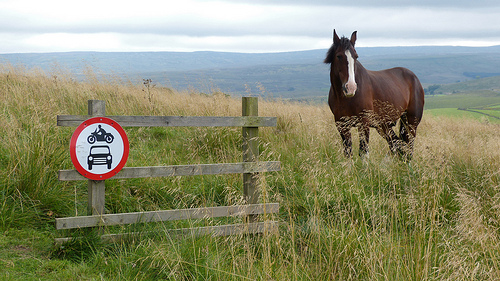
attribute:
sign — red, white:
[69, 121, 126, 180]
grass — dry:
[41, 63, 496, 274]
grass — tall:
[6, 61, 493, 279]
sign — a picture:
[67, 116, 132, 179]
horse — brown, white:
[323, 28, 425, 162]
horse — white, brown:
[308, 25, 444, 175]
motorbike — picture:
[82, 123, 120, 147]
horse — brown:
[328, 35, 424, 158]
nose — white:
[338, 47, 360, 96]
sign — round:
[66, 111, 134, 186]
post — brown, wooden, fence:
[46, 94, 217, 237]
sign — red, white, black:
[64, 117, 131, 183]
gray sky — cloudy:
[4, 1, 497, 49]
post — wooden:
[55, 96, 281, 249]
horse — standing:
[321, 33, 425, 169]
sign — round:
[71, 98, 119, 198]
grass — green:
[348, 170, 412, 233]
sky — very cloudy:
[1, 0, 499, 55]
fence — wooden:
[50, 83, 308, 261]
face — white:
[342, 50, 355, 93]